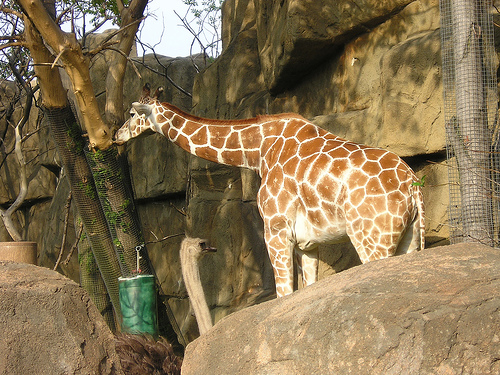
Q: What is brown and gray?
A: The rocks.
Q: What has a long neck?
A: The giraffe.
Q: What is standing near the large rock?
A: The ostrich.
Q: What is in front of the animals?
A: A large gray rock.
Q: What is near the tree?
A: A green container.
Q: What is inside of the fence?
A: Green leaves.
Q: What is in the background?
A: A large rock wall.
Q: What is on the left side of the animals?
A: A dead tree.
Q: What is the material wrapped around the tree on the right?
A: Metal fencing.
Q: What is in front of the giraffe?
A: The rock.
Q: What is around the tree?
A: The wire mesh fence.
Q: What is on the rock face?
A: Cracks.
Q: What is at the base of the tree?
A: Some chicken wire.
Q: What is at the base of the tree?
A: Some chicken wire.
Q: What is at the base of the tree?
A: Some chicken wire.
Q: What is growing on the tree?
A: Vine.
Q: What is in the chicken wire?
A: Some twigs.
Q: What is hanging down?
A: Some leafless branches.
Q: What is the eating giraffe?
A: Tan and brown.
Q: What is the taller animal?
A: The giraffe.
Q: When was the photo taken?
A: Daytime.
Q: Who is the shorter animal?
A: The ostrich.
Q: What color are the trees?
A: Brown.